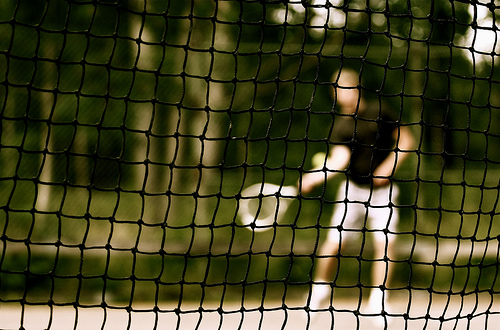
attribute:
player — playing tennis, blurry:
[296, 68, 414, 312]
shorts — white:
[327, 178, 399, 244]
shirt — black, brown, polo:
[326, 99, 404, 190]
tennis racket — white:
[236, 181, 299, 232]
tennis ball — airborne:
[313, 151, 326, 168]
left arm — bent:
[371, 101, 415, 182]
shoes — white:
[305, 276, 387, 320]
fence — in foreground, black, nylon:
[0, 1, 499, 329]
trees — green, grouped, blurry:
[0, 0, 500, 301]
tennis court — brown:
[0, 297, 500, 329]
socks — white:
[312, 277, 387, 294]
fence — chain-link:
[0, 28, 499, 301]